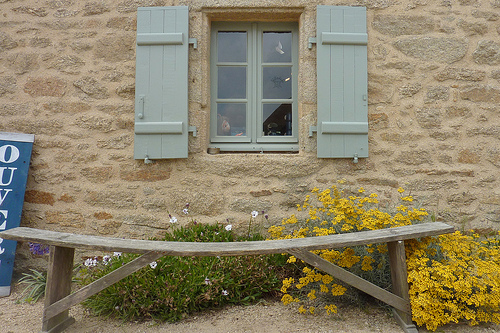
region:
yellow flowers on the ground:
[413, 241, 498, 323]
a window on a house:
[202, 16, 303, 153]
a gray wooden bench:
[0, 216, 454, 325]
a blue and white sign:
[3, 130, 39, 297]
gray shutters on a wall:
[312, 2, 370, 163]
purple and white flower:
[79, 254, 248, 316]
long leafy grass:
[17, 260, 50, 310]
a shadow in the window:
[259, 90, 299, 147]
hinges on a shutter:
[187, 23, 202, 141]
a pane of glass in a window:
[216, 28, 248, 62]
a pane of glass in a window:
[261, 30, 288, 61]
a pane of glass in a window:
[217, 64, 246, 98]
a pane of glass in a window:
[263, 65, 291, 97]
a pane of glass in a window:
[220, 103, 245, 135]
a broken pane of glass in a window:
[263, 103, 292, 135]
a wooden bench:
[8, 217, 463, 329]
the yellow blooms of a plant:
[271, 188, 498, 325]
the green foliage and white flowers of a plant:
[53, 208, 286, 311]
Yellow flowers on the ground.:
[269, 179, 498, 327]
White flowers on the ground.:
[86, 180, 261, 290]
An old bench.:
[1, 223, 457, 332]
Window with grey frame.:
[208, 15, 308, 152]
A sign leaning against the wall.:
[0, 121, 37, 294]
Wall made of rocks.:
[373, 15, 490, 177]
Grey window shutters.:
[137, 1, 372, 163]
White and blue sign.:
[0, 134, 32, 291]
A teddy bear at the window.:
[213, 98, 254, 133]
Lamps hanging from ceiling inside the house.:
[271, 33, 291, 60]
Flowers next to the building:
[288, 181, 483, 331]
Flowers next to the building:
[100, 185, 267, 300]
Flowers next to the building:
[455, 235, 485, 272]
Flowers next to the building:
[300, 186, 425, 229]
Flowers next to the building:
[142, 258, 222, 295]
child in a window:
[216, 102, 246, 149]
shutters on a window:
[132, 3, 379, 165]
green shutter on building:
[316, 3, 381, 165]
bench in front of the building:
[7, 216, 455, 321]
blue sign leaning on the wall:
[0, 128, 37, 300]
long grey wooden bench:
[7, 205, 467, 330]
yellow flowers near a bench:
[285, 173, 495, 329]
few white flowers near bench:
[55, 185, 286, 328]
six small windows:
[197, 0, 302, 168]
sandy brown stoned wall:
[3, 1, 120, 122]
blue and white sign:
[0, 122, 35, 303]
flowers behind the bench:
[7, 182, 497, 330]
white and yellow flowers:
[75, 195, 490, 325]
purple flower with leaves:
[5, 225, 75, 330]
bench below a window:
[1, 1, 451, 330]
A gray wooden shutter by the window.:
[130, 3, 202, 171]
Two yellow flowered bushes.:
[266, 177, 498, 332]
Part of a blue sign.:
[1, 126, 39, 305]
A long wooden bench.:
[2, 219, 459, 329]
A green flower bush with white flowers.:
[76, 195, 301, 326]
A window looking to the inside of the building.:
[196, 3, 310, 172]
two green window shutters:
[132, 6, 371, 167]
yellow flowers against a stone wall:
[275, 182, 498, 327]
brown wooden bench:
[2, 220, 455, 327]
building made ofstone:
[2, 3, 494, 237]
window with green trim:
[200, 3, 302, 155]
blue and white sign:
[1, 131, 37, 295]